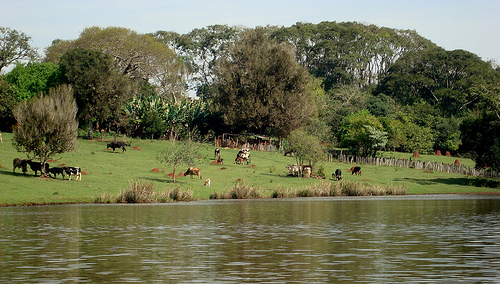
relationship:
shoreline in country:
[10, 175, 475, 200] [3, 11, 500, 233]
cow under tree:
[61, 166, 83, 182] [11, 90, 85, 157]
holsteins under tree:
[287, 163, 356, 183] [286, 132, 332, 167]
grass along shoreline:
[122, 181, 400, 202] [0, 191, 499, 208]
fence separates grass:
[341, 154, 468, 178] [0, 132, 500, 204]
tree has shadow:
[464, 115, 499, 173] [404, 171, 492, 198]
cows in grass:
[331, 168, 344, 181] [0, 132, 500, 204]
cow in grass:
[213, 147, 221, 161] [0, 132, 500, 204]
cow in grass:
[61, 166, 83, 182] [0, 132, 500, 204]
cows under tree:
[287, 163, 356, 183] [286, 132, 332, 167]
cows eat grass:
[331, 168, 344, 181] [122, 181, 400, 202]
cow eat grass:
[213, 147, 221, 161] [122, 181, 400, 202]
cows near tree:
[331, 168, 344, 181] [286, 132, 332, 167]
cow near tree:
[213, 147, 221, 161] [154, 139, 206, 171]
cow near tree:
[61, 166, 83, 182] [11, 90, 85, 157]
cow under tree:
[66, 162, 83, 181] [11, 90, 85, 157]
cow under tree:
[302, 163, 315, 179] [286, 132, 332, 167]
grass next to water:
[122, 181, 400, 202] [12, 209, 494, 276]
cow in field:
[61, 166, 83, 182] [6, 132, 482, 196]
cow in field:
[285, 163, 304, 177] [6, 132, 482, 196]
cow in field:
[183, 166, 203, 180] [6, 132, 482, 196]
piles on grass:
[144, 165, 185, 184] [122, 181, 400, 202]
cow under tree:
[28, 156, 48, 178] [11, 90, 85, 157]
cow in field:
[105, 139, 129, 156] [6, 132, 482, 196]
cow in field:
[212, 147, 223, 164] [6, 132, 482, 196]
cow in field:
[236, 149, 252, 165] [6, 132, 482, 196]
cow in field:
[349, 167, 364, 177] [6, 132, 482, 196]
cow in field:
[186, 165, 207, 181] [6, 132, 482, 196]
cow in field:
[9, 158, 31, 172] [6, 132, 482, 196]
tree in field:
[11, 90, 85, 157] [6, 132, 482, 196]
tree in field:
[154, 139, 206, 171] [6, 132, 482, 196]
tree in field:
[286, 132, 332, 167] [6, 132, 482, 196]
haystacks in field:
[132, 142, 186, 182] [6, 132, 482, 196]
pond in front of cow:
[12, 209, 494, 276] [285, 163, 304, 177]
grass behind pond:
[122, 181, 400, 202] [12, 209, 494, 276]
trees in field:
[282, 124, 330, 178] [6, 132, 482, 196]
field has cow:
[6, 132, 482, 196] [285, 163, 304, 177]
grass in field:
[85, 154, 142, 185] [6, 132, 482, 196]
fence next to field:
[341, 154, 468, 178] [6, 132, 482, 196]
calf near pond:
[202, 178, 215, 190] [12, 209, 494, 276]